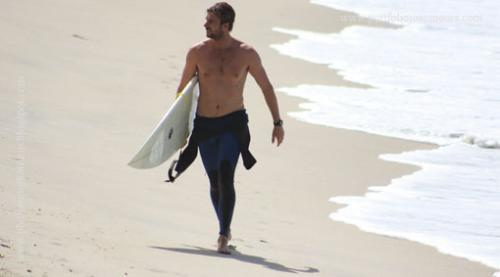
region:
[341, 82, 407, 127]
edge of a shore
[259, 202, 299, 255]
part of some sand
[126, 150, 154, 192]
tip of a boardf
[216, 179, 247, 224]
part of a costume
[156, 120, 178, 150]
part of a board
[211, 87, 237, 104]
part of a stomach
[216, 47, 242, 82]
part of a chest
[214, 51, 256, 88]
part of a chest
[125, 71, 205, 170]
a long white surfboard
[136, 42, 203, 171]
under an armpit is a surfboard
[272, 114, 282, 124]
black sports watch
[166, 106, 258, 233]
blue and black wetsuit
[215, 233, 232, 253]
bare white foot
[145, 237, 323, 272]
a shadow under man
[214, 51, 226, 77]
a hairy patch on a chest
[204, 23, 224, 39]
a beard on a man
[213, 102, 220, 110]
a belly button on a man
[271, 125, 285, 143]
a hand of a man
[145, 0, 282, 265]
One man on the beach.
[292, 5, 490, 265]
Waves crashing on the beach.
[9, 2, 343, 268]
The sand is tan.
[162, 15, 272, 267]
The man's wet suit is half off.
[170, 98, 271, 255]
The wet suit is blue and black.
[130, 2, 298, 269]
Man carrying a surfboard.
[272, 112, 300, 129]
Watch on the man's wrist.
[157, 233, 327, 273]
Shadow cast in the sand.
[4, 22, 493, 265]
Photo taken during the summer.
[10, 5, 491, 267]
Photo taken during the day.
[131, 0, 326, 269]
the surfer is walking on the beach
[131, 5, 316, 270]
the surfer is carrying his board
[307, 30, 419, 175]
lots of white foam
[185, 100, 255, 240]
the surfer is wearing a wetsuit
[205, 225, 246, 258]
the surfer is barefoot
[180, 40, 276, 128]
the surfer is not wearing shirt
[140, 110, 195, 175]
the board is white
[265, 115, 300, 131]
the man is wearing a watch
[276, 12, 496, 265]
waves are coming in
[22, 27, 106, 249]
lots of smooth sand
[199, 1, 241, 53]
the man's hair is brown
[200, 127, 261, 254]
the man's wetsuit is blue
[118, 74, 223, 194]
the man's surfboard is white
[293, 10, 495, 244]
the waves are white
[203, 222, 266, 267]
the man's foot has sand on it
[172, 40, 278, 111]
half of the wetsuit is off the man's body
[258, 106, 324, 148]
the man is wearing a watch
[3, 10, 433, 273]
the sand is brown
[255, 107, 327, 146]
the man's watch is black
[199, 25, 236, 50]
the man has a beard